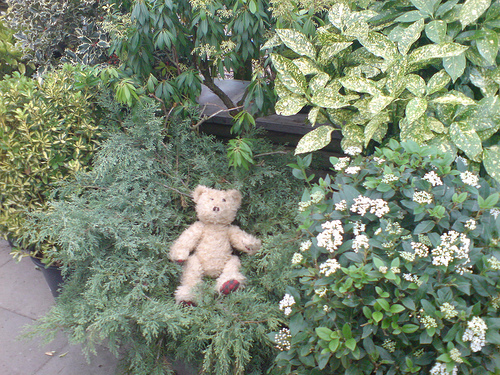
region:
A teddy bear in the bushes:
[164, 181, 264, 303]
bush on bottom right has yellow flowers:
[275, 154, 498, 373]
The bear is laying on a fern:
[38, 112, 315, 374]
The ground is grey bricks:
[1, 238, 251, 373]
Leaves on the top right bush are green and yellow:
[268, 5, 498, 176]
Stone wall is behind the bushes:
[156, 69, 400, 204]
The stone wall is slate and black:
[178, 71, 366, 181]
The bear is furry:
[163, 183, 266, 313]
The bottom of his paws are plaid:
[173, 281, 241, 308]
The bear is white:
[168, 176, 265, 304]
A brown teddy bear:
[162, 173, 260, 309]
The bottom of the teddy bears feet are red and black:
[175, 250, 243, 309]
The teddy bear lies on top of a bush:
[156, 152, 271, 354]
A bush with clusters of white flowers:
[298, 162, 478, 347]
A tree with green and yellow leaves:
[273, 34, 468, 148]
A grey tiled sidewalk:
[3, 243, 123, 365]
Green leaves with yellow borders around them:
[15, 16, 131, 71]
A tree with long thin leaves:
[124, 12, 291, 154]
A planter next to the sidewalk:
[11, 18, 482, 348]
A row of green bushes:
[12, 38, 460, 347]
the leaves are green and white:
[275, 26, 486, 137]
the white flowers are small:
[303, 178, 498, 365]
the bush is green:
[4, 67, 89, 197]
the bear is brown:
[152, 169, 266, 320]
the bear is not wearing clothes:
[163, 169, 273, 366]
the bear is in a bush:
[145, 148, 280, 328]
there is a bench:
[96, 42, 421, 144]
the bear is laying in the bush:
[130, 137, 281, 322]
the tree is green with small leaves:
[118, 12, 295, 119]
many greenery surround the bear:
[16, 9, 498, 339]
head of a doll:
[199, 193, 234, 221]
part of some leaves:
[355, 276, 417, 358]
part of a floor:
[31, 332, 66, 359]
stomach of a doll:
[188, 227, 220, 277]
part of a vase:
[34, 258, 56, 282]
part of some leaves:
[291, 60, 338, 120]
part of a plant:
[363, 267, 408, 319]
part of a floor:
[2, 304, 41, 349]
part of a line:
[4, 296, 43, 330]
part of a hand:
[161, 228, 183, 272]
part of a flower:
[332, 215, 401, 267]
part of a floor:
[18, 305, 75, 337]